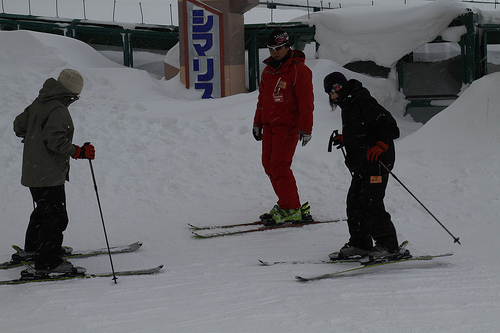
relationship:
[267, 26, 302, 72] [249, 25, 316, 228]
head of man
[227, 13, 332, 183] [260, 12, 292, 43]
man has hat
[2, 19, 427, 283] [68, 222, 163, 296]
people on ski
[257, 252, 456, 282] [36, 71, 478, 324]
skis on snow